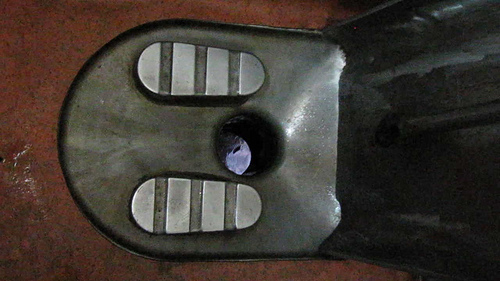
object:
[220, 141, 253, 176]
water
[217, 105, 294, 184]
hole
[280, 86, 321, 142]
light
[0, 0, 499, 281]
ground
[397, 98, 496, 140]
pipe